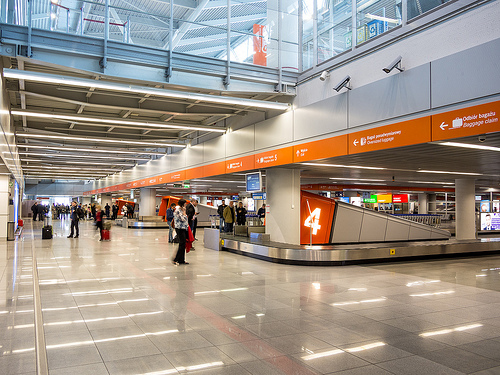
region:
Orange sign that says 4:
[298, 187, 345, 247]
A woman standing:
[160, 193, 202, 270]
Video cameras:
[316, 53, 412, 100]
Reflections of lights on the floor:
[54, 275, 484, 367]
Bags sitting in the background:
[36, 220, 63, 245]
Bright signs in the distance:
[368, 187, 418, 217]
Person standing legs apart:
[60, 197, 86, 246]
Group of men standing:
[212, 189, 252, 240]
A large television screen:
[238, 171, 276, 201]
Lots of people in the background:
[26, 193, 73, 220]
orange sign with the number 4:
[288, 188, 339, 259]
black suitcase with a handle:
[34, 212, 61, 244]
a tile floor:
[36, 249, 159, 366]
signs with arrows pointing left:
[341, 107, 492, 156]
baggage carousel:
[220, 226, 490, 264]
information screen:
[241, 170, 271, 199]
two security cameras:
[328, 58, 431, 105]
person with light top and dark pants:
[165, 194, 200, 274]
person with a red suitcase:
[90, 201, 118, 256]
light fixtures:
[0, 61, 295, 182]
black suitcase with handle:
[37, 213, 52, 239]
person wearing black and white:
[170, 195, 190, 262]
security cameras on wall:
[330, 55, 410, 95]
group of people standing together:
[211, 195, 246, 230]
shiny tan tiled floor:
[2, 216, 497, 368]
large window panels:
[0, 0, 497, 85]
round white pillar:
[451, 170, 476, 245]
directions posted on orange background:
[345, 107, 495, 147]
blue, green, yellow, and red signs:
[335, 185, 415, 205]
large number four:
[298, 196, 330, 239]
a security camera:
[329, 67, 364, 97]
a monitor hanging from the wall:
[237, 162, 277, 200]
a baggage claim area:
[196, 180, 462, 285]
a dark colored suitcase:
[34, 211, 61, 244]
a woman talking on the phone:
[158, 192, 216, 288]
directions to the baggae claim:
[333, 107, 446, 164]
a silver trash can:
[5, 210, 36, 244]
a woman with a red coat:
[159, 194, 210, 268]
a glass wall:
[19, 2, 313, 110]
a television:
[463, 206, 498, 247]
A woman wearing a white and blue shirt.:
[167, 194, 194, 270]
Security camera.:
[372, 54, 413, 81]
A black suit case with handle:
[33, 212, 56, 247]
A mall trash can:
[3, 218, 17, 246]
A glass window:
[1, 0, 298, 77]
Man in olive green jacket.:
[222, 198, 236, 232]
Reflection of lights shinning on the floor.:
[283, 328, 406, 365]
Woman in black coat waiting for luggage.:
[235, 199, 248, 225]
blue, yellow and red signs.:
[360, 191, 417, 208]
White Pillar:
[448, 176, 479, 248]